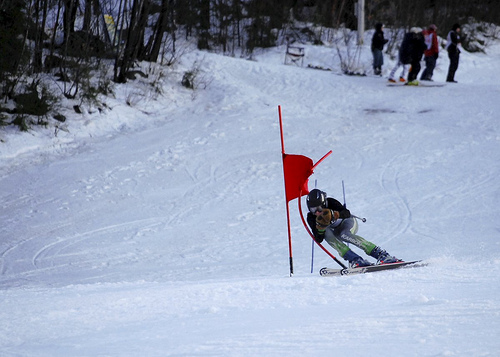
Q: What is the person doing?
A: Downhill skiing.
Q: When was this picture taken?
A: Daytime.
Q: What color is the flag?
A: Red.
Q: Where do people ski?
A: In the mountains.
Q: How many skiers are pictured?
A: One.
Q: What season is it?
A: Winter.